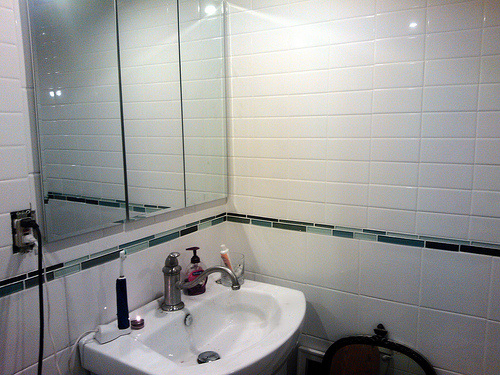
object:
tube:
[219, 244, 234, 272]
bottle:
[182, 245, 207, 296]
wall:
[225, 1, 499, 375]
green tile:
[376, 236, 423, 247]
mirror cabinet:
[17, 0, 127, 243]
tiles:
[421, 55, 480, 86]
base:
[93, 320, 130, 344]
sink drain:
[160, 248, 183, 312]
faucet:
[160, 251, 240, 311]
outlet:
[9, 206, 37, 254]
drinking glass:
[219, 251, 248, 286]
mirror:
[16, 0, 226, 245]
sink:
[145, 290, 283, 367]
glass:
[65, 123, 108, 175]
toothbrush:
[114, 248, 134, 331]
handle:
[114, 276, 129, 328]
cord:
[20, 217, 45, 375]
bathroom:
[0, 1, 500, 373]